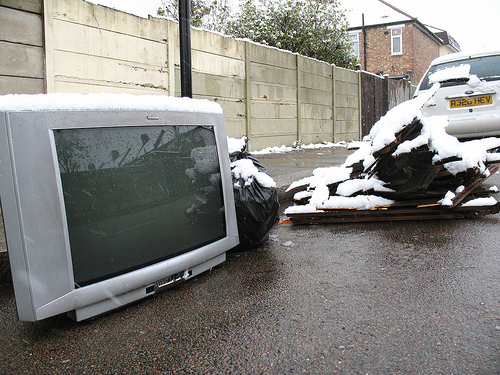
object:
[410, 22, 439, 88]
wall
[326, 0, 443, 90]
house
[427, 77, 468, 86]
wiper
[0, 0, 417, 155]
fence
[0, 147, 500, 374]
pavement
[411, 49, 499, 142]
car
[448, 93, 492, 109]
plate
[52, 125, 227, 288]
reflections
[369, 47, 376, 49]
bricks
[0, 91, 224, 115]
snow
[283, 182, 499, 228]
boxes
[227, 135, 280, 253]
trash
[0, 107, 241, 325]
television set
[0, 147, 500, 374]
ground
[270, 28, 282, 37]
leaves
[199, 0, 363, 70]
tree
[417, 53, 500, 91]
back window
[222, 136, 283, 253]
trash bag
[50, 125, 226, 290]
television screen